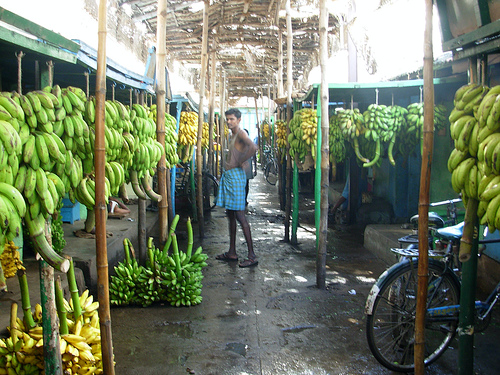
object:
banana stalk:
[446, 82, 499, 237]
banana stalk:
[362, 103, 397, 169]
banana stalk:
[328, 105, 371, 164]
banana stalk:
[291, 106, 319, 161]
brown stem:
[29, 241, 88, 283]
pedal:
[477, 288, 498, 330]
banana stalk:
[179, 109, 199, 164]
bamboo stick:
[95, 41, 117, 375]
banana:
[0, 84, 499, 375]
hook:
[375, 89, 379, 105]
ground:
[107, 170, 417, 370]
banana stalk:
[148, 214, 195, 306]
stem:
[27, 220, 71, 273]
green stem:
[26, 219, 71, 272]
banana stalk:
[10, 253, 86, 372]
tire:
[365, 257, 458, 374]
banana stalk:
[26, 83, 163, 274]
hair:
[224, 108, 242, 119]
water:
[158, 307, 430, 372]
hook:
[17, 51, 22, 96]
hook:
[41, 59, 54, 90]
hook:
[86, 73, 90, 97]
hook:
[112, 84, 115, 101]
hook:
[375, 89, 378, 105]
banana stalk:
[122, 237, 138, 304]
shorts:
[213, 167, 249, 211]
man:
[214, 107, 259, 267]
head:
[224, 108, 242, 129]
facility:
[0, 0, 500, 374]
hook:
[476, 54, 488, 87]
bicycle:
[364, 198, 500, 374]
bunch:
[445, 83, 500, 232]